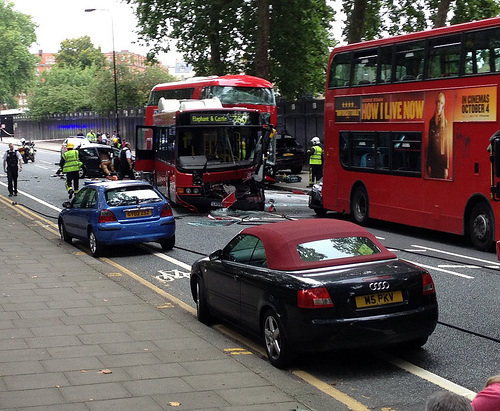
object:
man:
[57, 142, 84, 198]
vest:
[60, 150, 85, 171]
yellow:
[391, 290, 403, 299]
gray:
[17, 248, 72, 307]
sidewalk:
[17, 246, 131, 343]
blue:
[70, 204, 89, 233]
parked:
[34, 180, 124, 241]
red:
[377, 175, 459, 222]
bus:
[322, 20, 499, 246]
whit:
[148, 248, 187, 296]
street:
[406, 240, 465, 293]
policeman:
[3, 140, 25, 198]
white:
[155, 249, 180, 272]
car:
[188, 217, 439, 367]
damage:
[185, 175, 262, 211]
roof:
[150, 75, 267, 88]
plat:
[125, 209, 155, 220]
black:
[209, 269, 238, 294]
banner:
[182, 110, 259, 128]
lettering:
[189, 115, 245, 124]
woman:
[197, 132, 210, 159]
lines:
[410, 242, 499, 268]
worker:
[54, 144, 84, 196]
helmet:
[65, 140, 75, 152]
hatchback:
[190, 216, 441, 370]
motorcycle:
[18, 136, 38, 164]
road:
[185, 227, 221, 245]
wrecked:
[186, 168, 287, 223]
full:
[223, 19, 351, 30]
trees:
[246, 0, 336, 101]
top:
[243, 218, 371, 243]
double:
[322, 37, 427, 192]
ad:
[334, 85, 498, 124]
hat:
[309, 134, 324, 144]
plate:
[354, 288, 406, 308]